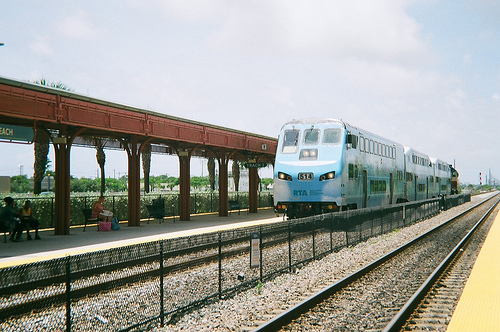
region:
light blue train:
[249, 117, 484, 224]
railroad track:
[292, 176, 498, 313]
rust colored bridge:
[2, 76, 276, 174]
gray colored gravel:
[201, 249, 349, 322]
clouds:
[64, 12, 441, 138]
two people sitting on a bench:
[6, 196, 51, 246]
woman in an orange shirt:
[90, 196, 127, 239]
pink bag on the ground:
[95, 217, 123, 232]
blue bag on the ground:
[109, 198, 132, 233]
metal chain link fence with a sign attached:
[16, 221, 348, 270]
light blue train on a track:
[1, 118, 460, 322]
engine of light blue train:
[272, 119, 403, 226]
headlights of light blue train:
[276, 169, 335, 181]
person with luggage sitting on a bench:
[81, 194, 121, 231]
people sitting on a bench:
[1, 195, 42, 242]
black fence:
[0, 190, 472, 330]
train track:
[239, 190, 497, 330]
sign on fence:
[249, 229, 261, 269]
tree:
[18, 74, 78, 193]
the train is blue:
[255, 106, 483, 241]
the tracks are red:
[32, 79, 241, 174]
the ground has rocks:
[243, 291, 282, 314]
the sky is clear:
[198, 29, 410, 96]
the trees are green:
[68, 176, 98, 187]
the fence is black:
[146, 240, 243, 310]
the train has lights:
[271, 151, 349, 196]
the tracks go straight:
[337, 253, 402, 329]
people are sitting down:
[3, 194, 55, 244]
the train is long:
[266, 102, 470, 225]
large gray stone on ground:
[225, 267, 257, 291]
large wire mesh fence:
[92, 242, 249, 294]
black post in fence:
[145, 232, 175, 316]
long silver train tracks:
[346, 243, 443, 320]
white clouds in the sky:
[170, 35, 366, 82]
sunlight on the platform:
[48, 239, 198, 273]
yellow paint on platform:
[469, 283, 491, 330]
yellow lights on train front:
[273, 165, 371, 189]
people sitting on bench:
[8, 194, 51, 235]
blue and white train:
[249, 106, 486, 258]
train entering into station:
[210, 101, 477, 252]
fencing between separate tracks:
[32, 190, 494, 285]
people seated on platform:
[5, 175, 140, 236]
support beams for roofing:
[25, 140, 256, 225]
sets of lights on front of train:
[275, 140, 336, 185]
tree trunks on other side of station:
[26, 145, 258, 207]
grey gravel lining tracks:
[131, 216, 386, 313]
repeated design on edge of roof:
[15, 90, 260, 160]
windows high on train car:
[347, 115, 407, 160]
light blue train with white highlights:
[275, 98, 456, 209]